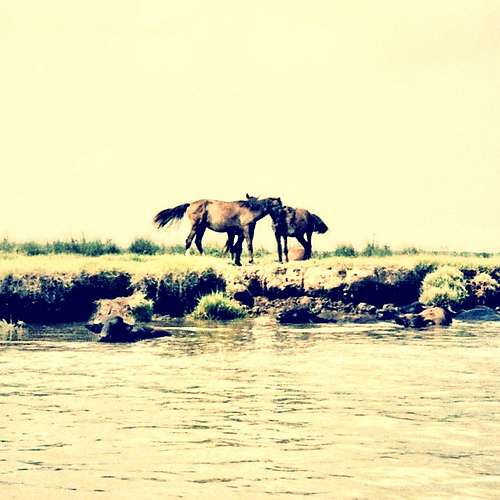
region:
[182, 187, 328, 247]
Two horses playing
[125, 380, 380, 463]
Waters in a river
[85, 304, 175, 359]
A cow in the water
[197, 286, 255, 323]
Grass on the river bank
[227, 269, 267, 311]
A rock boulder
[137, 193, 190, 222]
Tail of a horse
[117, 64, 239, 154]
Cloudy skies in the photo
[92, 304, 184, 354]
A cow wading in the water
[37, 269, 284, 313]
A river bank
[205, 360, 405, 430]
Water flowing in a river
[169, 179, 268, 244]
A horse in the photo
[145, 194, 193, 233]
A horse tail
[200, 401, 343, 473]
Water in the river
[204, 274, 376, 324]
A river bank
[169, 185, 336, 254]
Two horses playing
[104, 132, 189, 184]
Cloudy skies in the picture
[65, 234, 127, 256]
Grass in the photo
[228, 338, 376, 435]
Water flowing in the river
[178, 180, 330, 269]
Two horses in the photo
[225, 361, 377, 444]
A water pan in the photo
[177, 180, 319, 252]
Two horses playing in the field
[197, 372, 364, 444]
Water in the photo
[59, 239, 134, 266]
Grass in the field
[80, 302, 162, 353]
Cow in the water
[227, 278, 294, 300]
Rock boulders at the bank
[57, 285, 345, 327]
A river bank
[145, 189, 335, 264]
two brown horses on green field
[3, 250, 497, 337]
green grass bank of body of water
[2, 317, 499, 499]
body of water before marsh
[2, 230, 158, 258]
tufts of grass on green field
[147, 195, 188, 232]
brown horse tail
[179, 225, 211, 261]
rear back horse legs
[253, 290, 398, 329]
rocks at edge of embankment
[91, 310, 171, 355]
animal swimming in body of water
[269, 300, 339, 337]
cow swimming in water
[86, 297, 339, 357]
two black cows swimming in the water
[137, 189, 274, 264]
brown horse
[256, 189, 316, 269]
brown horse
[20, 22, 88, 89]
white clouds in blue sky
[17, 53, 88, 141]
white clouds in blue sky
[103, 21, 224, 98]
white clouds in blue sky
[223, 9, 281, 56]
white clouds in blue sky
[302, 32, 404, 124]
white clouds in blue sky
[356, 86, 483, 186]
white clouds in blue sky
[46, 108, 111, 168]
white clouds in blue sky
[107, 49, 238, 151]
white clouds in blue sky